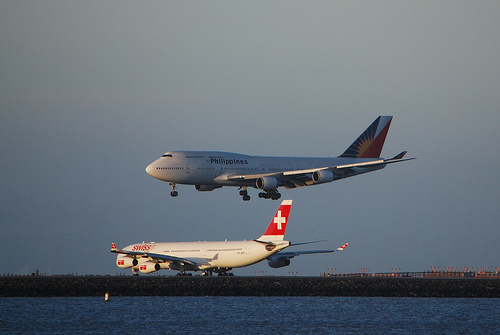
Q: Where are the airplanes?
A: In the air.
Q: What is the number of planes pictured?
A: 2.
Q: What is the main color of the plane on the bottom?
A: White.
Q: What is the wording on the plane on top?
A: Philippines.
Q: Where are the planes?
A: Above the water.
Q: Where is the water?
A: Below plane.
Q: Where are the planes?
A: Sky.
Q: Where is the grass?
A: Right side of planes.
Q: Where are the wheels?
A: Beneath plane.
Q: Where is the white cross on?
A: Plane tail.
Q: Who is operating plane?
A: Pilot.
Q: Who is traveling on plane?
A: Passengers.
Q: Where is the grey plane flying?
A: Above the white plane.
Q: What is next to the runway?
A: Ocean.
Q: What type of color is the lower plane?
A: White.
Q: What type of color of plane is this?
A: Silver.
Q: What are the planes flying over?
A: Water.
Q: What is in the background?
A: A rocky coast.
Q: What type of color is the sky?
A: Gray.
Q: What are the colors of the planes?
A: White.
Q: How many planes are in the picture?
A: Two.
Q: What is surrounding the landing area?
A: Water.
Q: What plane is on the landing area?
A: Swiss.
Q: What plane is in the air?
A: Philippines.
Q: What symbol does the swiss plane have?
A: Cross.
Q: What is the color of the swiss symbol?
A: White.